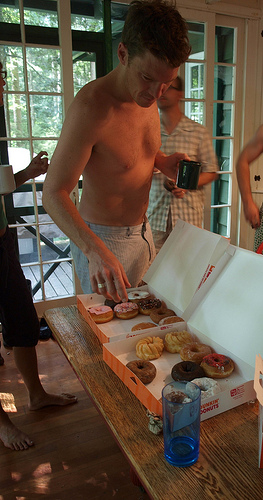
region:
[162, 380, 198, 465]
the cup is blue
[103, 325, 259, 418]
a carton of dunkin donut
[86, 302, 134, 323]
a donut has strawberry icing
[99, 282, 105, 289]
the man has a ring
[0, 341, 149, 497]
the floor is made of wood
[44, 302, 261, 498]
the table is made of wood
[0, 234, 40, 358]
the man is wearing shorts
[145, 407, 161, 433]
a crumbled up piece of napkin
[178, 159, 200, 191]
the man is holding a cup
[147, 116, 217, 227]
the man is wearing a plaid shirt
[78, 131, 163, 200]
man wearing no shirt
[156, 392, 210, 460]
blue plastic cup is empty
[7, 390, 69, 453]
pair of shoe less feet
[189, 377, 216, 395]
powdered doughnut in box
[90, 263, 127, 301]
man reaching for doughnut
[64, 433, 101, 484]
brown hardwood dusty floor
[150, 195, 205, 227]
man wearing beige shirt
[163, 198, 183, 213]
shirt is beige plaid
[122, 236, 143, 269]
man wears gray pants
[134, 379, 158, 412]
front of doughnut box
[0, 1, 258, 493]
Group of men having breakfast.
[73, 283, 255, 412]
Two boxes of variety of donuts.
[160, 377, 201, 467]
Empty blue glass on the wooden table.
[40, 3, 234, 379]
Man selecting a donut.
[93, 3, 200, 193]
Man holding a cup of coffee.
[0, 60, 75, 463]
Man standing on a hardwood floor.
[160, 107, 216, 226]
Man wearing white and green plaid shirt.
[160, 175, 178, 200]
Man holding a brown donut.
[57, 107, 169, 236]
The man is shirtless.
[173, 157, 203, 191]
black glass coffee cup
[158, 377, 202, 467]
clear blue drinking glass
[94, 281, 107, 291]
man's gold ring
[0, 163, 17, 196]
white glass coffee cup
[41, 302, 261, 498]
brown wood table doughnuts on it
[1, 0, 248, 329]
white french style wood doors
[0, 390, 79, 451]
Man's bare feet standing on wood floor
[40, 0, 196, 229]
man not wearing a shirt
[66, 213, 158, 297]
man's light colored striped Bermuda style shorts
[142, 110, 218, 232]
man's short sleeved button up shirt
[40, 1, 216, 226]
a man with no shirt on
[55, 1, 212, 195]
a man holding a cup of coffee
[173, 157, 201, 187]
a green coffee mug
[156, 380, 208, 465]
a blue drink glass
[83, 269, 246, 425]
two boxes of dougnuts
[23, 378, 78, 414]
the bare foot of a man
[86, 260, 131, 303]
the hand of a man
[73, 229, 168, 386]
a hand reaching for a doughnut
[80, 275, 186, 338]
tasty dunkin donuts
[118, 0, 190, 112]
a man with short hair